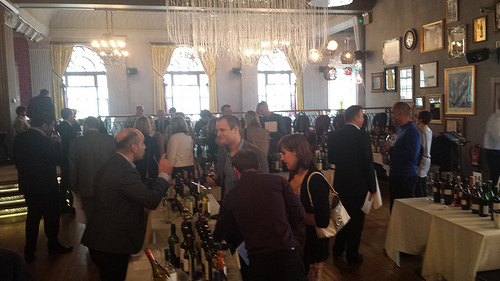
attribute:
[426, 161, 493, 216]
bottle — wine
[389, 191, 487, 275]
table — white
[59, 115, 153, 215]
man — bald, wearing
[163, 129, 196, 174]
jacket — white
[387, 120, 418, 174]
shirt — blue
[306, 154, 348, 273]
drapes — yellow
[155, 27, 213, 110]
window — light, bright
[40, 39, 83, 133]
curtain — long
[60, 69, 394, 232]
people — standing